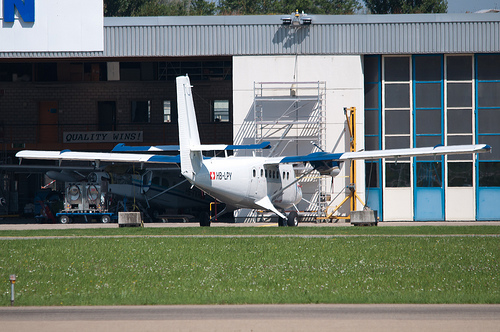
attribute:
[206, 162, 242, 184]
letter — black 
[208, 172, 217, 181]
print — small , red , white 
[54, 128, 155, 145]
banner — white 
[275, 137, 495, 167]
aircraft wing — blue , white 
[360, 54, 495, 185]
windows — small 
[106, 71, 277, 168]
tail — white , blue 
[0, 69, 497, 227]
jet — white , blue